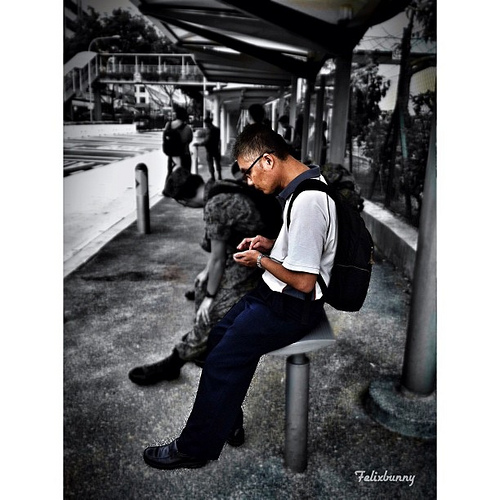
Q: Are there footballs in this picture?
A: No, there are no footballs.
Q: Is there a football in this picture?
A: No, there are no footballs.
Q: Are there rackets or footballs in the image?
A: No, there are no footballs or rackets.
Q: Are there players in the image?
A: No, there are no players.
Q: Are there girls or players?
A: No, there are no players or girls.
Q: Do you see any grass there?
A: Yes, there is grass.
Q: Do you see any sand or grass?
A: Yes, there is grass.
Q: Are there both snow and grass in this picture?
A: No, there is grass but no snow.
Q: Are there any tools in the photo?
A: No, there are no tools.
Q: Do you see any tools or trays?
A: No, there are no tools or trays.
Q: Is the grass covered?
A: Yes, the grass is covered.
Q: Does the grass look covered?
A: Yes, the grass is covered.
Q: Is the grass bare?
A: No, the grass is covered.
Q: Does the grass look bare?
A: No, the grass is covered.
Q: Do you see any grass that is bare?
A: No, there is grass but it is covered.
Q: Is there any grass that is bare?
A: No, there is grass but it is covered.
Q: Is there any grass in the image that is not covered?
A: No, there is grass but it is covered.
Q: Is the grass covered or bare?
A: The grass is covered.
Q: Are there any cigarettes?
A: No, there are no cigarettes.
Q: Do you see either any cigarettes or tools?
A: No, there are no cigarettes or tools.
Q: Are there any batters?
A: No, there are no batters.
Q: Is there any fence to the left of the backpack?
A: No, there is a soldier to the left of the backpack.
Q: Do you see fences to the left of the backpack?
A: No, there is a soldier to the left of the backpack.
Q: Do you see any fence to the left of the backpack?
A: No, there is a soldier to the left of the backpack.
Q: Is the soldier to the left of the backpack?
A: Yes, the soldier is to the left of the backpack.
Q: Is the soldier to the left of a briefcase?
A: No, the soldier is to the left of the backpack.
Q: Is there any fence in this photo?
A: No, there are no fences.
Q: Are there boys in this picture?
A: No, there are no boys.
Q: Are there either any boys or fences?
A: No, there are no boys or fences.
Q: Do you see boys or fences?
A: No, there are no boys or fences.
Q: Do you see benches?
A: Yes, there is a bench.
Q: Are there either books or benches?
A: Yes, there is a bench.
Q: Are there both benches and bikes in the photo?
A: No, there is a bench but no bikes.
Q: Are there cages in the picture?
A: No, there are no cages.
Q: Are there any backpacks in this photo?
A: Yes, there is a backpack.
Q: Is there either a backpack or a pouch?
A: Yes, there is a backpack.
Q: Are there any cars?
A: No, there are no cars.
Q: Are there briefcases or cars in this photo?
A: No, there are no cars or briefcases.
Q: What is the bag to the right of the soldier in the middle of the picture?
A: The bag is a backpack.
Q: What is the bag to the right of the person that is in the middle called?
A: The bag is a backpack.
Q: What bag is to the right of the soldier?
A: The bag is a backpack.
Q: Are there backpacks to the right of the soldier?
A: Yes, there is a backpack to the right of the soldier.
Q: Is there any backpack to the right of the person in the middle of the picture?
A: Yes, there is a backpack to the right of the soldier.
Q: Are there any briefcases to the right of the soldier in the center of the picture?
A: No, there is a backpack to the right of the soldier.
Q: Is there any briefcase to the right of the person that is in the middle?
A: No, there is a backpack to the right of the soldier.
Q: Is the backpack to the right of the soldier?
A: Yes, the backpack is to the right of the soldier.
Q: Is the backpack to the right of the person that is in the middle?
A: Yes, the backpack is to the right of the soldier.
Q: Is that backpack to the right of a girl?
A: No, the backpack is to the right of the soldier.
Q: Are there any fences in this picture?
A: No, there are no fences.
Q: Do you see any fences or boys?
A: No, there are no fences or boys.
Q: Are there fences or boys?
A: No, there are no fences or boys.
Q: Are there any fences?
A: No, there are no fences.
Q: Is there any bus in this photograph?
A: No, there are no buses.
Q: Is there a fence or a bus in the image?
A: No, there are no buses or fences.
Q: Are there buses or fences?
A: No, there are no buses or fences.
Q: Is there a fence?
A: No, there are no fences.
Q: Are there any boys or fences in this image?
A: No, there are no fences or boys.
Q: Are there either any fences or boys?
A: No, there are no fences or boys.